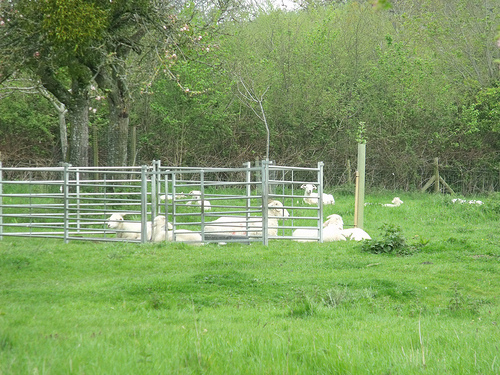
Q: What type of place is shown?
A: It is a field.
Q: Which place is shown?
A: It is a field.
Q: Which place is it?
A: It is a field.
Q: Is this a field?
A: Yes, it is a field.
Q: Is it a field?
A: Yes, it is a field.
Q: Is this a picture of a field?
A: Yes, it is showing a field.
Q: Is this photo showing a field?
A: Yes, it is showing a field.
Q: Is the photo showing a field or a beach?
A: It is showing a field.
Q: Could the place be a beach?
A: No, it is a field.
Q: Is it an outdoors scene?
A: Yes, it is outdoors.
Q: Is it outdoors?
A: Yes, it is outdoors.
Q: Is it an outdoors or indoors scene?
A: It is outdoors.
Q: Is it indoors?
A: No, it is outdoors.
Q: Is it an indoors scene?
A: No, it is outdoors.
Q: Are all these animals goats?
A: No, there are both sheep and goats.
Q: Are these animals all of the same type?
A: No, there are both sheep and goats.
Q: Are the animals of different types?
A: Yes, they are sheep and goats.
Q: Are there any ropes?
A: No, there are no ropes.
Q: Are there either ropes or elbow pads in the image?
A: No, there are no ropes or elbow pads.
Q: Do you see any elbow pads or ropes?
A: No, there are no ropes or elbow pads.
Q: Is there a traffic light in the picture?
A: No, there are no traffic lights.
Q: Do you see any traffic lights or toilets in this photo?
A: No, there are no traffic lights or toilets.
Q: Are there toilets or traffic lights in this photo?
A: No, there are no traffic lights or toilets.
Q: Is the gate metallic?
A: Yes, the gate is metallic.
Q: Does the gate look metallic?
A: Yes, the gate is metallic.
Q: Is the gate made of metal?
A: Yes, the gate is made of metal.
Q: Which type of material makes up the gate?
A: The gate is made of metal.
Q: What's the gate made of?
A: The gate is made of metal.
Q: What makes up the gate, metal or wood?
A: The gate is made of metal.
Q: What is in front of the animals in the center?
A: The gate is in front of the goats.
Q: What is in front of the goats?
A: The gate is in front of the goats.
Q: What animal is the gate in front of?
A: The gate is in front of the goats.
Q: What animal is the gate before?
A: The gate is in front of the goats.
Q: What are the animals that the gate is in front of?
A: The animals are goats.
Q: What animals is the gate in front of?
A: The gate is in front of the goats.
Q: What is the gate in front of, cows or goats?
A: The gate is in front of goats.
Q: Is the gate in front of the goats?
A: Yes, the gate is in front of the goats.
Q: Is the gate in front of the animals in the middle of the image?
A: Yes, the gate is in front of the goats.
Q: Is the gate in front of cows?
A: No, the gate is in front of the goats.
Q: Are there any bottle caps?
A: No, there are no bottle caps.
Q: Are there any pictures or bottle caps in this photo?
A: No, there are no bottle caps or pictures.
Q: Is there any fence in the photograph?
A: Yes, there is a fence.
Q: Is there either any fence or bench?
A: Yes, there is a fence.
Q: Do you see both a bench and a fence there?
A: No, there is a fence but no benches.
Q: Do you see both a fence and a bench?
A: No, there is a fence but no benches.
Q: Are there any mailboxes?
A: No, there are no mailboxes.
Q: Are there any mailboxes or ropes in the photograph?
A: No, there are no mailboxes or ropes.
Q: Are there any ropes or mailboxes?
A: No, there are no mailboxes or ropes.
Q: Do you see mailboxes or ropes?
A: No, there are no mailboxes or ropes.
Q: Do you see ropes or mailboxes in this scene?
A: No, there are no mailboxes or ropes.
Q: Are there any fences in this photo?
A: Yes, there is a fence.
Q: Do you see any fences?
A: Yes, there is a fence.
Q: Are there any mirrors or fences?
A: Yes, there is a fence.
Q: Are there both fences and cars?
A: No, there is a fence but no cars.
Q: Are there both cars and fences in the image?
A: No, there is a fence but no cars.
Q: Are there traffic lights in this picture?
A: No, there are no traffic lights.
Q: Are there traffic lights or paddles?
A: No, there are no traffic lights or paddles.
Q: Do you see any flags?
A: No, there are no flags.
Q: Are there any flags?
A: No, there are no flags.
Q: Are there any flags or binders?
A: No, there are no flags or binders.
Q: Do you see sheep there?
A: Yes, there is a sheep.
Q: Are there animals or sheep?
A: Yes, there is a sheep.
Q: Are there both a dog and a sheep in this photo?
A: No, there is a sheep but no dogs.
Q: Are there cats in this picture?
A: No, there are no cats.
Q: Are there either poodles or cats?
A: No, there are no cats or poodles.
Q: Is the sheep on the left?
A: Yes, the sheep is on the left of the image.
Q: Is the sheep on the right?
A: No, the sheep is on the left of the image.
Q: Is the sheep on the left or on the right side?
A: The sheep is on the left of the image.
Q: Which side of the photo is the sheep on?
A: The sheep is on the left of the image.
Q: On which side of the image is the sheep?
A: The sheep is on the left of the image.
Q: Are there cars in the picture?
A: No, there are no cars.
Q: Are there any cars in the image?
A: No, there are no cars.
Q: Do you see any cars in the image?
A: No, there are no cars.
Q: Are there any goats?
A: Yes, there are goats.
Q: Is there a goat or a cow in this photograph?
A: Yes, there are goats.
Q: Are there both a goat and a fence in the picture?
A: Yes, there are both a goat and a fence.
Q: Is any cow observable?
A: No, there are no cows.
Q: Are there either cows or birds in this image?
A: No, there are no cows or birds.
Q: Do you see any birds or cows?
A: No, there are no cows or birds.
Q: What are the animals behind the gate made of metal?
A: The animals are goats.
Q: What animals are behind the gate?
A: The animals are goats.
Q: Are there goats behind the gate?
A: Yes, there are goats behind the gate.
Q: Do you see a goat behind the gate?
A: Yes, there are goats behind the gate.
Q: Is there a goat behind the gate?
A: Yes, there are goats behind the gate.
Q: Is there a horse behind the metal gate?
A: No, there are goats behind the gate.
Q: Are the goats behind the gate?
A: Yes, the goats are behind the gate.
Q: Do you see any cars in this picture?
A: No, there are no cars.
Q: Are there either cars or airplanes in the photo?
A: No, there are no cars or airplanes.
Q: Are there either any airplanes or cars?
A: No, there are no cars or airplanes.